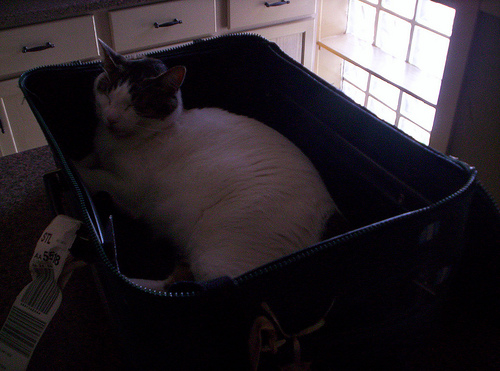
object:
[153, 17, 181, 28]
handle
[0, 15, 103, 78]
drawer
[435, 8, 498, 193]
wall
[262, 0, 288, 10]
handle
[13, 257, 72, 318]
bar code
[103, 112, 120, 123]
nose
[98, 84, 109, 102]
eye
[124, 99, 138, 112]
eye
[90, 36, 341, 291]
cat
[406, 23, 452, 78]
pane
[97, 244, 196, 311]
zipper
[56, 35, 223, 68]
zipper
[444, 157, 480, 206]
edge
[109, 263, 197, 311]
edge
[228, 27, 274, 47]
edge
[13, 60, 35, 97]
edge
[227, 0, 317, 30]
drawer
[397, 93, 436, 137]
pane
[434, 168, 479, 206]
zipper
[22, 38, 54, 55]
handle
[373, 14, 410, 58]
pane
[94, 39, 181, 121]
head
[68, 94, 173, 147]
whiskers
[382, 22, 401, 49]
light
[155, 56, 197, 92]
cat ear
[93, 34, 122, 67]
cat ear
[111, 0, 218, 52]
drawer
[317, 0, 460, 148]
window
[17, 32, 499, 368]
black suitcase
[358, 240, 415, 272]
side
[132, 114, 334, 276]
fur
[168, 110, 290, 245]
body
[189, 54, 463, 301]
ground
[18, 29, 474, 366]
box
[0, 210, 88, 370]
paper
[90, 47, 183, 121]
patch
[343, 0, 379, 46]
panels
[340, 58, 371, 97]
pane